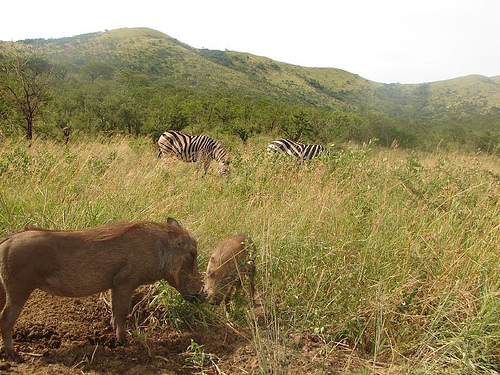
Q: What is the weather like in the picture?
A: It is clear.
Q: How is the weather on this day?
A: It is clear.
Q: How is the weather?
A: It is clear.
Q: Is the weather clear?
A: Yes, it is clear.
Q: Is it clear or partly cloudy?
A: It is clear.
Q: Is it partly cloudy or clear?
A: It is clear.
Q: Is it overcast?
A: No, it is clear.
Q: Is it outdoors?
A: Yes, it is outdoors.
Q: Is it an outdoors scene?
A: Yes, it is outdoors.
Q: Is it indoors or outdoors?
A: It is outdoors.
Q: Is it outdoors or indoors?
A: It is outdoors.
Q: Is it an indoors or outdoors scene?
A: It is outdoors.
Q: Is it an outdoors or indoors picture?
A: It is outdoors.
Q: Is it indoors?
A: No, it is outdoors.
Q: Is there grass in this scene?
A: Yes, there is grass.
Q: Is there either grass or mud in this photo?
A: Yes, there is grass.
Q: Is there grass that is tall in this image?
A: Yes, there is tall grass.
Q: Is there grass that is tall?
A: Yes, there is grass that is tall.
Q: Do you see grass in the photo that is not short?
A: Yes, there is tall grass.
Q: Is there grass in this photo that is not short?
A: Yes, there is tall grass.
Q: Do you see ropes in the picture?
A: No, there are no ropes.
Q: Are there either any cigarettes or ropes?
A: No, there are no ropes or cigarettes.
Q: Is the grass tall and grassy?
A: Yes, the grass is tall and grassy.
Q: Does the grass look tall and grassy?
A: Yes, the grass is tall and grassy.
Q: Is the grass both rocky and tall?
A: No, the grass is tall but grassy.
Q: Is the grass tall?
A: Yes, the grass is tall.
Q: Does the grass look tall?
A: Yes, the grass is tall.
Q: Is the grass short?
A: No, the grass is tall.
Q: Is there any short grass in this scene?
A: No, there is grass but it is tall.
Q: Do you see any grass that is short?
A: No, there is grass but it is tall.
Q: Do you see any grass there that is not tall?
A: No, there is grass but it is tall.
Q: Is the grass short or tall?
A: The grass is tall.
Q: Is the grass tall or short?
A: The grass is tall.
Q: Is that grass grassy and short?
A: No, the grass is grassy but tall.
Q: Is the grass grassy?
A: Yes, the grass is grassy.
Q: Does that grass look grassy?
A: Yes, the grass is grassy.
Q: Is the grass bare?
A: No, the grass is grassy.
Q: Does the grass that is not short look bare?
A: No, the grass is grassy.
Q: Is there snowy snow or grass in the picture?
A: No, there is grass but it is grassy.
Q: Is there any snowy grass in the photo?
A: No, there is grass but it is grassy.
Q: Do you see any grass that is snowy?
A: No, there is grass but it is grassy.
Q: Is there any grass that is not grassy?
A: No, there is grass but it is grassy.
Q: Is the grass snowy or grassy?
A: The grass is grassy.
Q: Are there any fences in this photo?
A: No, there are no fences.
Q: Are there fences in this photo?
A: No, there are no fences.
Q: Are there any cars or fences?
A: No, there are no fences or cars.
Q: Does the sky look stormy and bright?
A: No, the sky is bright but clear.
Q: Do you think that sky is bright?
A: Yes, the sky is bright.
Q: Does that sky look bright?
A: Yes, the sky is bright.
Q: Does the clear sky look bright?
A: Yes, the sky is bright.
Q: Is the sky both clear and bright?
A: Yes, the sky is clear and bright.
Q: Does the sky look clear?
A: Yes, the sky is clear.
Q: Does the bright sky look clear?
A: Yes, the sky is clear.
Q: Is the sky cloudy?
A: No, the sky is clear.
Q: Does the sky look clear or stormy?
A: The sky is clear.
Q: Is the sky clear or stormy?
A: The sky is clear.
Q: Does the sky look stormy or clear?
A: The sky is clear.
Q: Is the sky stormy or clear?
A: The sky is clear.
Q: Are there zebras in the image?
A: Yes, there is a zebra.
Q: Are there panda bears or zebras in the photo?
A: Yes, there is a zebra.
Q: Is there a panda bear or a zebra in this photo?
A: Yes, there is a zebra.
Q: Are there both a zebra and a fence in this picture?
A: No, there is a zebra but no fences.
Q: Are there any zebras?
A: Yes, there is a zebra.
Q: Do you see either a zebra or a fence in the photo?
A: Yes, there is a zebra.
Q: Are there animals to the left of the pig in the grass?
A: Yes, there are animals to the left of the pig.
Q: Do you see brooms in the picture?
A: No, there are no brooms.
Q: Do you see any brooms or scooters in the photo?
A: No, there are no brooms or scooters.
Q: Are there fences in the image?
A: No, there are no fences.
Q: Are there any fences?
A: No, there are no fences.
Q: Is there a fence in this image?
A: No, there are no fences.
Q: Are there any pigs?
A: Yes, there is a pig.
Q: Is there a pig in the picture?
A: Yes, there is a pig.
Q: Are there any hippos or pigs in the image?
A: Yes, there is a pig.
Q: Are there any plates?
A: No, there are no plates.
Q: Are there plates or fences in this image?
A: No, there are no plates or fences.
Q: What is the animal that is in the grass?
A: The animal is a pig.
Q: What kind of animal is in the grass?
A: The animal is a pig.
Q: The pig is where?
A: The pig is in the grass.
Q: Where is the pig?
A: The pig is in the grass.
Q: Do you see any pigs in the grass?
A: Yes, there is a pig in the grass.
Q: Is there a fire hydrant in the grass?
A: No, there is a pig in the grass.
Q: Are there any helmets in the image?
A: No, there are no helmets.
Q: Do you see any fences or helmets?
A: No, there are no helmets or fences.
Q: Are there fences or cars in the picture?
A: No, there are no fences or cars.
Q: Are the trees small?
A: Yes, the trees are small.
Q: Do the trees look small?
A: Yes, the trees are small.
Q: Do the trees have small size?
A: Yes, the trees are small.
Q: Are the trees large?
A: No, the trees are small.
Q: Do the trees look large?
A: No, the trees are small.